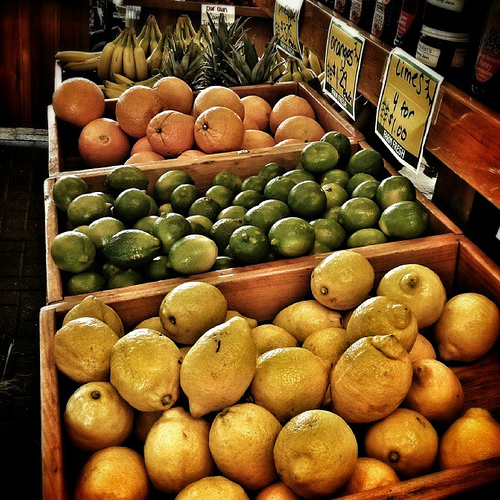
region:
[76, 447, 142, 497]
a fruit in a box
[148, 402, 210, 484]
a fruit in a box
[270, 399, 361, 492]
a fruit in a box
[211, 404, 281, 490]
a fruit in a box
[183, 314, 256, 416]
a fruit in a box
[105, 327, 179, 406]
a fruit in a box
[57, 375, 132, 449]
a fruit in a box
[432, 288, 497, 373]
a fruit in a box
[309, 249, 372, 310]
a fruit in a box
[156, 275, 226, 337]
a fruit in a box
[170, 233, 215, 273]
a fruit in a box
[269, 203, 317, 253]
a fruit in a box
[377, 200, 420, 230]
a fruit in a box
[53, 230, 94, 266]
a fruit in a box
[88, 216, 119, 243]
a fruit in a box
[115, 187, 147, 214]
a fruit in a box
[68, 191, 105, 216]
a fruit in a box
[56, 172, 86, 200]
a fruit in a box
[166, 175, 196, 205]
a fruit in a box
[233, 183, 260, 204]
a fruit in a box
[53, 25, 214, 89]
bananas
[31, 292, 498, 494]
big, shiny lemons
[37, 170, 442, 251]
limes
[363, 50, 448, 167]
a sign that says limes 4 for a dollar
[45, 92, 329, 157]
big oranges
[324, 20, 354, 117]
a sign advertising oranges for $1.29 each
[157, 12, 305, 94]
pineapples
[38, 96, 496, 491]
Wooden boxes full of fresh fruit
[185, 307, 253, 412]
A lemon with a black line in it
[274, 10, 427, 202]
three signs advertising farm fresh fruit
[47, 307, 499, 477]
lemons in a wooden bin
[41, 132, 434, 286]
limes in a wooden bin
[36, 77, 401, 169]
oranges in a produce bin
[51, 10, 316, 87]
bananas and pineapples for sale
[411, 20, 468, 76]
jar with white lid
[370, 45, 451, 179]
yellow and black sign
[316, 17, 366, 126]
yellow, black and white handwritten sign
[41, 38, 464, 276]
fruit for sale in a store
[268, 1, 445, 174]
three signs taped to piece of wood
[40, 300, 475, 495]
pile of yellow lemons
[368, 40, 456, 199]
sign says limes four for one dollar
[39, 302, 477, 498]
box of lemons in picture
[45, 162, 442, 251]
box of limes in photo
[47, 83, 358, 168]
boxes of oranges in photo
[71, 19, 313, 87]
box of oranges in photo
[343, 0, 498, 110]
jars of preserves on shelf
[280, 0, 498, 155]
shelf above fruit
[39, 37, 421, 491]
four boxes of fruit in photo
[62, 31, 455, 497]
five different kinds of fruit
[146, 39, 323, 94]
pineapples in photo